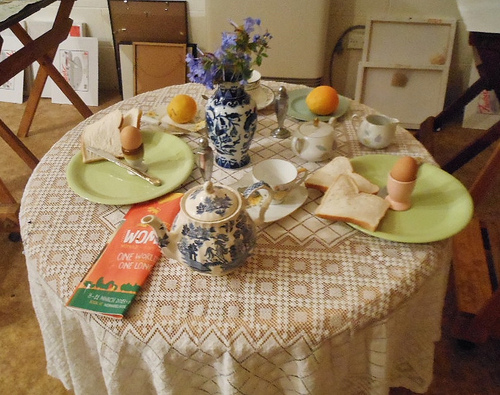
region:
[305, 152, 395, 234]
Bread on a plate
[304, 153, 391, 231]
Bread is on a plate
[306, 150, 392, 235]
Bread on a green plate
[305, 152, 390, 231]
Bread is on a green plate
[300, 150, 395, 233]
Bread on a round green plate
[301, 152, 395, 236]
Bread is on a round green plate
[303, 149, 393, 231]
Slices of bread on a plate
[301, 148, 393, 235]
Slices of bread on a green plate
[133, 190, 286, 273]
the tea pot on the table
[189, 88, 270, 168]
the vase on the table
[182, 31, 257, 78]
flowers in the vase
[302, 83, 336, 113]
the orange on the plate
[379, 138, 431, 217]
the brown egg in the cup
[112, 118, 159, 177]
the brown egg in the cup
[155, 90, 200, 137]
the orange beside the plate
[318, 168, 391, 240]
the slice of bread on the plate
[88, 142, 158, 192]
the knife on the plate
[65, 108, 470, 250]
green plates on table.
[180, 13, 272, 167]
Flowers are in the vase.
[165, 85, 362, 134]
oranges are on small plates.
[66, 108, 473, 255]
two slices of bread on plates.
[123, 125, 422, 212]
brown eggs in egg holders.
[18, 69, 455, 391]
white table cloth on table.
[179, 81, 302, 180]
silver salt an pepper shakers on the table.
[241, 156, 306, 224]
white cup on saucer.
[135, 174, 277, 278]
white an blue tea kettle on the table.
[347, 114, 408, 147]
white creamer is on the table.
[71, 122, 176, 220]
a plat on a table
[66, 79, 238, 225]
a green plate on a table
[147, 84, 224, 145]
a orange on a table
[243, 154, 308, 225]
a cup on a table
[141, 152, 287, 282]
a te pot on a table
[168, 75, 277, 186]
a vase on a table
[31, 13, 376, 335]
food on a table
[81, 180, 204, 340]
a paper on a table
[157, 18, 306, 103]
flowers on a table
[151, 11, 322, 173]
flowers in a vase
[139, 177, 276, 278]
A blue and white tea kettle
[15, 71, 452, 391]
The table is round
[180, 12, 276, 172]
Purple flowers in a vase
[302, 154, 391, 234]
Two slices of toast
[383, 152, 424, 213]
A brown egg in a cup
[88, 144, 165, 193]
Butter knife on a plate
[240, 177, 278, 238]
The handle of a tea kettle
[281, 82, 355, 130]
A grapefruit on a plate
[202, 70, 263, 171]
The vase is blue and white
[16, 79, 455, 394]
The tablecloth is white